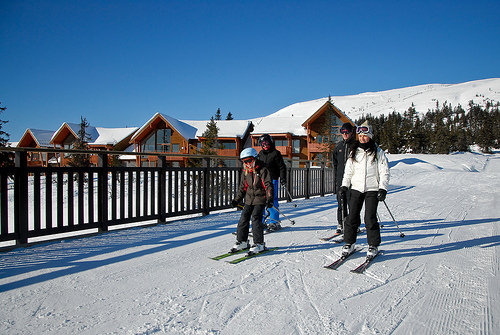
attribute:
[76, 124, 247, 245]
fence —  brown,  wooden,  of board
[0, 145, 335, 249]
fence — brown,  wooden, of board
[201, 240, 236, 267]
board —  wooden,  brown, for fence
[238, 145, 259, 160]
helmet —  White,  head's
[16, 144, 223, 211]
fence — of board,  brown,  wooden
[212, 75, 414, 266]
roof —  of houses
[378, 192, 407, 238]
pole — for Ski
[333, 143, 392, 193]
jacket —  white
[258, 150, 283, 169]
jacket —  black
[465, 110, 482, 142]
trees —  visible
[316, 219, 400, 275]
board —  brown ,  wooden ,  for fence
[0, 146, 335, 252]
wooden fence —  of board,  brown,  wooden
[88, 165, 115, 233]
wooden fence —  wooden,  of board,  brown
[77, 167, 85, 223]
fence board —  brown,  wooden,  fence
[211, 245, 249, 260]
green ski —  Green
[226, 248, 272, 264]
green ski —  Green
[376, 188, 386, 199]
glove —  black